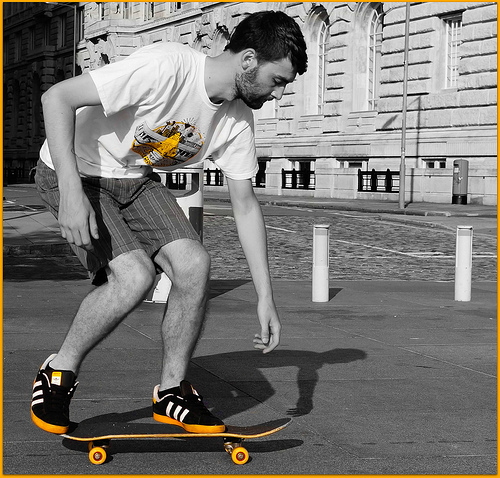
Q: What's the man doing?
A: Skateboarding.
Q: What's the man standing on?
A: Skateboard.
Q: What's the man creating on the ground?
A: Shadow.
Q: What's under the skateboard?
A: Wheels.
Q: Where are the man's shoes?
A: On the skateboard.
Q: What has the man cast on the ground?
A: A shadow.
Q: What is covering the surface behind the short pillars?
A: Grass.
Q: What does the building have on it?
A: Windows.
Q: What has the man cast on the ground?
A: A shadow.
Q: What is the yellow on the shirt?
A: A logo.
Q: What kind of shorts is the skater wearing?
A: Striped shorts.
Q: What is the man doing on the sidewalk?
A: Skateboarding.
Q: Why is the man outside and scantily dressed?
A: It is daytime.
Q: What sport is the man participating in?
A: Skateboarding.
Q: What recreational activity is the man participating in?
A: Riding a skate board.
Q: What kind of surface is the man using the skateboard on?
A: Concrete.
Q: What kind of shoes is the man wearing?
A: Tennis shoes.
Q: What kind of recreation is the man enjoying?
A: Riding a skateboard.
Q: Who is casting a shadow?
A: The man on the skateboard.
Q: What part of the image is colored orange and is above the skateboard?
A: The soles of the man's shoes.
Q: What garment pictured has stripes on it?
A: The man's shorts.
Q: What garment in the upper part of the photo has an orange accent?
A: The man's t-shirt.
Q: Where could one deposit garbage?
A: The trash can.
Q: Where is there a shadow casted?
A: On ground.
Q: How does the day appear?
A: Sunny and warm.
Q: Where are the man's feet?
A: On skateboard.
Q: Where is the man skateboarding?
A: On city street.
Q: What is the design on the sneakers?
A: Stripes.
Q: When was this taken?
A: Daytime.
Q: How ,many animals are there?
A: 0.